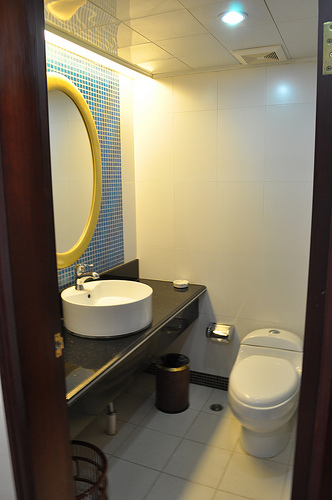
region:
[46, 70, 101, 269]
a wall mounted vanity mirror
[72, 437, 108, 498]
a wicker trash can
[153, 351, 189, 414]
a small brown trash can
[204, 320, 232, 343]
a toilet paper roll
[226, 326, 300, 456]
a white porcelain toilet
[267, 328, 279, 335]
a chrome toilet flush button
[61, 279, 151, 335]
a white porcelain sink basin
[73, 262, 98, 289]
a chrome bathroom sink faucet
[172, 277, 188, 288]
a cigarette ash tray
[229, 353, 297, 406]
a white plastic toilet seat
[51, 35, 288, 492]
this room is a bathroom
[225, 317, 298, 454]
a toilet is in the restroom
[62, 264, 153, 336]
the sink sits on the counter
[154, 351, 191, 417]
a small trash can is under the counter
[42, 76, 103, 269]
a mirror hangs on the wall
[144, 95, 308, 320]
the wall is made up of white tile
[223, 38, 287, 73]
a vent is on the ceiling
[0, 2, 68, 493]
pat of the door frame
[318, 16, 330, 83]
one of the doors hinges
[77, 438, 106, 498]
a small wire basket is under the sink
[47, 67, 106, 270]
the bathroom mirror is round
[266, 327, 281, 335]
a push of this button flushes the toilet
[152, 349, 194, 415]
the trash can in this bathroom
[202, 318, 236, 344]
the bath tissue dispenser in this bathroom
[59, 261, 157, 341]
this weird sink is set above the bathroom counter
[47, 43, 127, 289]
the bathroom wall is a blue mosaic pattern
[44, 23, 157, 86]
there is hidden lighting above the mirror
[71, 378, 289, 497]
the floor tile is white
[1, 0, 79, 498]
the door trim is dark red-brown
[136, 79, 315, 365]
the far wall is white tile like the floor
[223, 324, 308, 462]
white toilet with lid down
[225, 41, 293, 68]
fan in ceiling with white plastic cover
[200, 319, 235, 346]
silver toilet paper roll holder on wall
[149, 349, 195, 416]
dark gray colored garbage can with silver lid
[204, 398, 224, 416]
small drain in bathroom floor with silver cover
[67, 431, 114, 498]
brown clothes basket under counter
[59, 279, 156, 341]
white sink basin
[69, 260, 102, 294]
faucet in bathroom sink basin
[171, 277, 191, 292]
white glass ashtray on brown countertop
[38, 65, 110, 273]
oval mirror with yellow frame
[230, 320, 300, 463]
the toilet is white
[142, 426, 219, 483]
the floor is white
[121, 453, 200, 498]
the floor is tile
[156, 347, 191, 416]
the garbage can is metal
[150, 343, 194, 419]
the garbage can is black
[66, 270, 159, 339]
the sink is on top of the counter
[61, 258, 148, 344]
the sink is white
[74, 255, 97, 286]
the faucet is silver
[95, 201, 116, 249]
the wall is blue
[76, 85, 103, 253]
the mirror frame is yellow